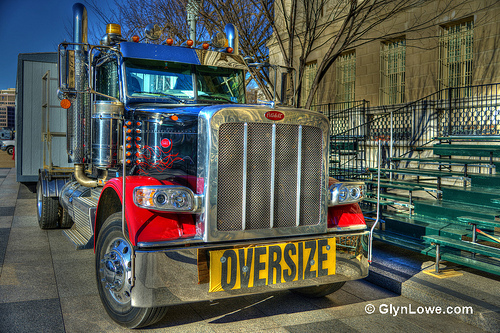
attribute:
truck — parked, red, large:
[24, 52, 348, 290]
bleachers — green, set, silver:
[366, 104, 498, 264]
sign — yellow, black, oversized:
[204, 243, 342, 289]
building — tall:
[279, 16, 499, 128]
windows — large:
[364, 29, 496, 102]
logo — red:
[263, 108, 302, 126]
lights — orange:
[131, 31, 245, 48]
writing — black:
[219, 249, 337, 286]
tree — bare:
[246, 16, 329, 106]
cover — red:
[101, 173, 170, 244]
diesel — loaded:
[69, 106, 242, 278]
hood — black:
[123, 99, 267, 115]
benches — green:
[369, 167, 478, 218]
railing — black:
[338, 112, 428, 153]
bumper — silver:
[128, 252, 379, 281]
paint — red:
[132, 214, 182, 234]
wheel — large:
[116, 226, 166, 322]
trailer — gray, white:
[10, 51, 68, 181]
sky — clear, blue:
[15, 11, 187, 50]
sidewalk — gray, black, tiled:
[386, 257, 498, 315]